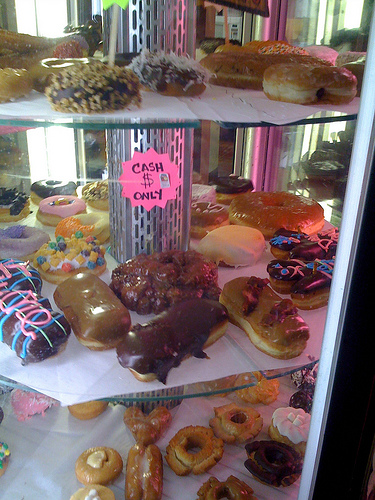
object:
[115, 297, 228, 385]
eclair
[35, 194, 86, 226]
doughnut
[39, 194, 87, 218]
icing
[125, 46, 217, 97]
doughnut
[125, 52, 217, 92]
coconut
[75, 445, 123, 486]
donut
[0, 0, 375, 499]
display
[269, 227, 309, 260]
cupcake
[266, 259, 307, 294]
cupcake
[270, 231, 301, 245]
icing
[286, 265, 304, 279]
icing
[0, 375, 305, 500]
paper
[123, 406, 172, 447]
pastry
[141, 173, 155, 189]
dollar sign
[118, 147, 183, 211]
sign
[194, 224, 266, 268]
pastry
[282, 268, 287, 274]
blue decorations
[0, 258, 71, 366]
pastry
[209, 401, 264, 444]
donut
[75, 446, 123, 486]
pastry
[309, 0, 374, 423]
pole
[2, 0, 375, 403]
glass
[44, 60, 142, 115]
doughnut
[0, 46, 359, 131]
tray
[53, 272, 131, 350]
donut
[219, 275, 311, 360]
donut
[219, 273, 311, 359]
bar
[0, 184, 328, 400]
tray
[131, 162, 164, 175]
cash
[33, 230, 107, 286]
donut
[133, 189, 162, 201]
only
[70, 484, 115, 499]
doughnut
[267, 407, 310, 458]
donut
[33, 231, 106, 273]
cereal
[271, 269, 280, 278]
frosting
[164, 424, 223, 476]
donut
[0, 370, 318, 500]
tray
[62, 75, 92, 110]
nuts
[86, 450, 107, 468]
filling